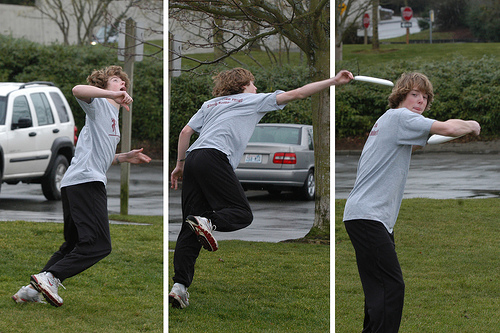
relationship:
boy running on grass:
[10, 65, 154, 310] [394, 205, 490, 296]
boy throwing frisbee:
[343, 72, 483, 333] [428, 125, 481, 146]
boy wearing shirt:
[342, 71, 472, 331] [344, 104, 410, 229]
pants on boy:
[346, 212, 405, 332] [348, 72, 467, 322]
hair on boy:
[386, 69, 435, 109] [342, 71, 472, 331]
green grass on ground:
[0, 194, 499, 331] [4, 224, 489, 331]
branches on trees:
[11, 3, 329, 61] [12, 1, 350, 70]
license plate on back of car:
[245, 154, 263, 164] [223, 114, 330, 212]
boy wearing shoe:
[10, 65, 154, 310] [29, 271, 65, 308]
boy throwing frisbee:
[342, 71, 472, 331] [423, 128, 466, 144]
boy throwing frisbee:
[169, 67, 353, 309] [352, 74, 395, 86]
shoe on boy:
[29, 271, 65, 308] [10, 65, 154, 310]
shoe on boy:
[182, 217, 220, 254] [165, 59, 311, 316]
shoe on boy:
[30, 269, 65, 309] [4, 60, 136, 315]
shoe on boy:
[5, 284, 45, 311] [4, 60, 136, 315]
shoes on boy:
[149, 206, 231, 313] [144, 40, 344, 282]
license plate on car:
[244, 152, 263, 163] [234, 122, 316, 199]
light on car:
[268, 148, 304, 169] [216, 112, 334, 203]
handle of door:
[25, 130, 38, 139] [26, 130, 38, 138]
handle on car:
[25, 130, 38, 139] [4, 78, 81, 201]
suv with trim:
[1, 86, 76, 203] [13, 153, 52, 171]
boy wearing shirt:
[10, 65, 154, 310] [54, 94, 126, 191]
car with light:
[232, 122, 317, 200] [272, 152, 296, 164]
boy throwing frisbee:
[343, 72, 483, 333] [352, 47, 417, 98]